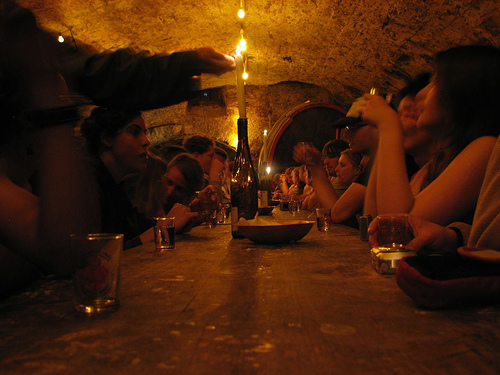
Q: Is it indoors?
A: Yes, it is indoors.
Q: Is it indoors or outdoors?
A: It is indoors.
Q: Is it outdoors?
A: No, it is indoors.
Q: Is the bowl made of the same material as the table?
A: Yes, both the bowl and the table are made of wood.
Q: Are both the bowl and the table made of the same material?
A: Yes, both the bowl and the table are made of wood.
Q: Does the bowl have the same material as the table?
A: Yes, both the bowl and the table are made of wood.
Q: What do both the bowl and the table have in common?
A: The material, both the bowl and the table are wooden.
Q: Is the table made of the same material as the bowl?
A: Yes, both the table and the bowl are made of wood.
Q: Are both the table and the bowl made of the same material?
A: Yes, both the table and the bowl are made of wood.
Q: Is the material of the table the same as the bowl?
A: Yes, both the table and the bowl are made of wood.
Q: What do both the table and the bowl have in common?
A: The material, both the table and the bowl are wooden.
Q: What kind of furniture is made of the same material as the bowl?
A: The table is made of the same material as the bowl.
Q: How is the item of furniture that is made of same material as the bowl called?
A: The piece of furniture is a table.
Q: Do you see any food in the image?
A: Yes, there is food.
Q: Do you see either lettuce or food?
A: Yes, there is food.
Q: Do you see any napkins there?
A: No, there are no napkins.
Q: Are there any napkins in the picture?
A: No, there are no napkins.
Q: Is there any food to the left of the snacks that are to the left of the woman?
A: Yes, there is food to the left of the snacks.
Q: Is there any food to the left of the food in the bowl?
A: Yes, there is food to the left of the snacks.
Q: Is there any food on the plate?
A: Yes, there is food on the plate.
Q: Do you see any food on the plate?
A: Yes, there is food on the plate.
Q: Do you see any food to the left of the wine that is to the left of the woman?
A: Yes, there is food to the left of the wine.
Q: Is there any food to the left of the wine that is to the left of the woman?
A: Yes, there is food to the left of the wine.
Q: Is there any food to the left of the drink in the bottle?
A: Yes, there is food to the left of the wine.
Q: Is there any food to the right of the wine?
A: No, the food is to the left of the wine.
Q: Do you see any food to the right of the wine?
A: No, the food is to the left of the wine.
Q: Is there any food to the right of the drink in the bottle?
A: No, the food is to the left of the wine.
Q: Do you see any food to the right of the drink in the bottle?
A: No, the food is to the left of the wine.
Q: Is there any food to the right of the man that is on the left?
A: Yes, there is food to the right of the man.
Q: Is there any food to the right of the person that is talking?
A: Yes, there is food to the right of the man.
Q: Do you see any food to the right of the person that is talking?
A: Yes, there is food to the right of the man.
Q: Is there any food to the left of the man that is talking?
A: No, the food is to the right of the man.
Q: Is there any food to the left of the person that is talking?
A: No, the food is to the right of the man.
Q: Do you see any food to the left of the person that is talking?
A: No, the food is to the right of the man.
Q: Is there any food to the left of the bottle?
A: Yes, there is food to the left of the bottle.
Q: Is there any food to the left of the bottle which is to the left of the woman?
A: Yes, there is food to the left of the bottle.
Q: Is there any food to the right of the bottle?
A: No, the food is to the left of the bottle.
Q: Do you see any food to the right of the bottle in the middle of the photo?
A: No, the food is to the left of the bottle.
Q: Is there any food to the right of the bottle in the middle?
A: No, the food is to the left of the bottle.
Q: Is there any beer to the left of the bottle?
A: No, there is food to the left of the bottle.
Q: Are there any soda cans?
A: No, there are no soda cans.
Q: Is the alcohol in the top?
A: Yes, the alcohol is in the top of the image.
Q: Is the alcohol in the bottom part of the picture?
A: No, the alcohol is in the top of the image.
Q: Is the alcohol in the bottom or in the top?
A: The alcohol is in the top of the image.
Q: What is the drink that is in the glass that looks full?
A: The drink is alcohol.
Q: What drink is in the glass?
A: The drink is alcohol.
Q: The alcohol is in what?
A: The alcohol is in the glass.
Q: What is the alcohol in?
A: The alcohol is in the glass.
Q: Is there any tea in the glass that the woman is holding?
A: No, there is alcohol in the glass.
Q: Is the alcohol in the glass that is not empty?
A: Yes, the alcohol is in the glass.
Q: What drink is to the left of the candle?
A: The drink is alcohol.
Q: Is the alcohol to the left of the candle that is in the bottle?
A: Yes, the alcohol is to the left of the candle.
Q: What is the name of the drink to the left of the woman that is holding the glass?
A: The drink is alcohol.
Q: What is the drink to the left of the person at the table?
A: The drink is alcohol.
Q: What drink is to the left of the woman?
A: The drink is alcohol.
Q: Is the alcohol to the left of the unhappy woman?
A: Yes, the alcohol is to the left of the woman.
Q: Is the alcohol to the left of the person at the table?
A: Yes, the alcohol is to the left of the woman.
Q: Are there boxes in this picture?
A: No, there are no boxes.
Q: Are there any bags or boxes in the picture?
A: No, there are no boxes or bags.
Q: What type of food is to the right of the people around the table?
A: The food is snacks.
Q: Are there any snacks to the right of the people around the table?
A: Yes, there are snacks to the right of the people.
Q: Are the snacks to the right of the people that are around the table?
A: Yes, the snacks are to the right of the people.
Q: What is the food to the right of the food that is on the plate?
A: The food is snacks.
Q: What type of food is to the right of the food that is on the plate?
A: The food is snacks.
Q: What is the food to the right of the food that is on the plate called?
A: The food is snacks.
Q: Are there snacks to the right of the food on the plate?
A: Yes, there are snacks to the right of the food.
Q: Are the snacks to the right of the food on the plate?
A: Yes, the snacks are to the right of the food.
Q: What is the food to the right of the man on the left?
A: The food is snacks.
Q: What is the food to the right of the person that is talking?
A: The food is snacks.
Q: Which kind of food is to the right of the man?
A: The food is snacks.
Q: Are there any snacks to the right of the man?
A: Yes, there are snacks to the right of the man.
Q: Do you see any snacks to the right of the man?
A: Yes, there are snacks to the right of the man.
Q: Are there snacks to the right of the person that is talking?
A: Yes, there are snacks to the right of the man.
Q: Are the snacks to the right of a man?
A: Yes, the snacks are to the right of a man.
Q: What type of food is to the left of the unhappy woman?
A: The food is snacks.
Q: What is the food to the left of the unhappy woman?
A: The food is snacks.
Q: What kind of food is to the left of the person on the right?
A: The food is snacks.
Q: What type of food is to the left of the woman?
A: The food is snacks.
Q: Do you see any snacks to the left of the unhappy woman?
A: Yes, there are snacks to the left of the woman.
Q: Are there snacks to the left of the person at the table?
A: Yes, there are snacks to the left of the woman.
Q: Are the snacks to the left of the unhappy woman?
A: Yes, the snacks are to the left of the woman.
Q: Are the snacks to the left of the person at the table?
A: Yes, the snacks are to the left of the woman.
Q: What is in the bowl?
A: The snacks are in the bowl.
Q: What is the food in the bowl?
A: The food is snacks.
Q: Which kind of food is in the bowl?
A: The food is snacks.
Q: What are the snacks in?
A: The snacks are in the bowl.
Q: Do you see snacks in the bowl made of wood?
A: Yes, there are snacks in the bowl.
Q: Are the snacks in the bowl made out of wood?
A: Yes, the snacks are in the bowl.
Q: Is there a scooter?
A: No, there are no scooters.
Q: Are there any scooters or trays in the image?
A: No, there are no scooters or trays.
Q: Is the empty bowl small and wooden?
A: Yes, the bowl is small and wooden.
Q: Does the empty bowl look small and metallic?
A: No, the bowl is small but wooden.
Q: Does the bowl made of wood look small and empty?
A: Yes, the bowl is small and empty.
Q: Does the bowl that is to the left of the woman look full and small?
A: No, the bowl is small but empty.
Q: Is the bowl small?
A: Yes, the bowl is small.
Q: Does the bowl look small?
A: Yes, the bowl is small.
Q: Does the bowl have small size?
A: Yes, the bowl is small.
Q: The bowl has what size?
A: The bowl is small.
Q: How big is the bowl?
A: The bowl is small.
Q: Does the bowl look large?
A: No, the bowl is small.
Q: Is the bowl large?
A: No, the bowl is small.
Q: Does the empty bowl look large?
A: No, the bowl is small.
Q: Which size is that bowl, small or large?
A: The bowl is small.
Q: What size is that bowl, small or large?
A: The bowl is small.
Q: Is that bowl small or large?
A: The bowl is small.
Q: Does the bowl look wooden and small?
A: Yes, the bowl is wooden and small.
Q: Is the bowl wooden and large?
A: No, the bowl is wooden but small.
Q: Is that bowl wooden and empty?
A: Yes, the bowl is wooden and empty.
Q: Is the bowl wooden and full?
A: No, the bowl is wooden but empty.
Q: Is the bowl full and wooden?
A: No, the bowl is wooden but empty.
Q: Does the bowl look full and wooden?
A: No, the bowl is wooden but empty.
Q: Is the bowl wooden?
A: Yes, the bowl is wooden.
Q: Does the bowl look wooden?
A: Yes, the bowl is wooden.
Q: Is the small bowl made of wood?
A: Yes, the bowl is made of wood.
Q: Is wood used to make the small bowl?
A: Yes, the bowl is made of wood.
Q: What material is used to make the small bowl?
A: The bowl is made of wood.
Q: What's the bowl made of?
A: The bowl is made of wood.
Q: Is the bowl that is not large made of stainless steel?
A: No, the bowl is made of wood.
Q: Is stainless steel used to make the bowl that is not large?
A: No, the bowl is made of wood.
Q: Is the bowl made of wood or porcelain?
A: The bowl is made of wood.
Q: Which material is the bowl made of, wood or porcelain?
A: The bowl is made of wood.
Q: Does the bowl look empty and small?
A: Yes, the bowl is empty and small.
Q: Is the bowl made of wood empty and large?
A: No, the bowl is empty but small.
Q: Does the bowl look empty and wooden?
A: Yes, the bowl is empty and wooden.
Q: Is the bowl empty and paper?
A: No, the bowl is empty but wooden.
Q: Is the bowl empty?
A: Yes, the bowl is empty.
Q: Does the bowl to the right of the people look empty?
A: Yes, the bowl is empty.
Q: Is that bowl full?
A: No, the bowl is empty.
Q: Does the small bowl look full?
A: No, the bowl is empty.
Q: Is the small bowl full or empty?
A: The bowl is empty.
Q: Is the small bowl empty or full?
A: The bowl is empty.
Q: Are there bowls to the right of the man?
A: Yes, there is a bowl to the right of the man.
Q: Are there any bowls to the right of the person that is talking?
A: Yes, there is a bowl to the right of the man.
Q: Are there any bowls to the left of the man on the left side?
A: No, the bowl is to the right of the man.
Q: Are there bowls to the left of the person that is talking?
A: No, the bowl is to the right of the man.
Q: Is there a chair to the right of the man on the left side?
A: No, there is a bowl to the right of the man.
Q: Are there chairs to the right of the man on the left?
A: No, there is a bowl to the right of the man.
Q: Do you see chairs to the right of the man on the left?
A: No, there is a bowl to the right of the man.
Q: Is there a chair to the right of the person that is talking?
A: No, there is a bowl to the right of the man.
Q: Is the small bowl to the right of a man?
A: Yes, the bowl is to the right of a man.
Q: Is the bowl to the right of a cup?
A: No, the bowl is to the right of a man.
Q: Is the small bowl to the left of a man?
A: No, the bowl is to the right of a man.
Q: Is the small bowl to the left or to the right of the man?
A: The bowl is to the right of the man.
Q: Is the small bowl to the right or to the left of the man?
A: The bowl is to the right of the man.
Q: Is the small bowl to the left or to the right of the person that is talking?
A: The bowl is to the right of the man.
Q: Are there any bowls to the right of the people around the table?
A: Yes, there is a bowl to the right of the people.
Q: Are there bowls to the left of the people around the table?
A: No, the bowl is to the right of the people.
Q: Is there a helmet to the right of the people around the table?
A: No, there is a bowl to the right of the people.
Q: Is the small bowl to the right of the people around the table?
A: Yes, the bowl is to the right of the people.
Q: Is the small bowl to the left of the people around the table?
A: No, the bowl is to the right of the people.